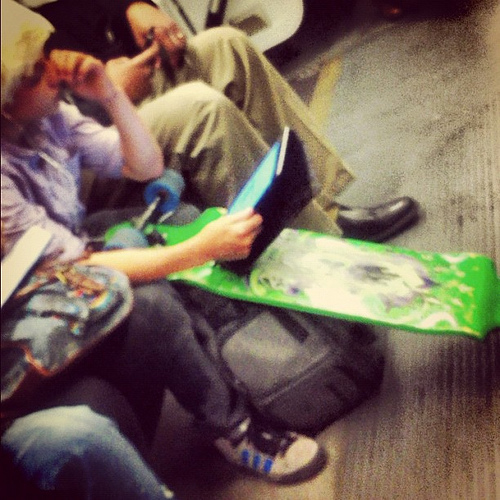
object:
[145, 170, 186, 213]
wheels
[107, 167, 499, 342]
skateboard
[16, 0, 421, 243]
man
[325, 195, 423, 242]
shoe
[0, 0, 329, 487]
boy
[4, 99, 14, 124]
earphones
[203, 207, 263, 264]
hand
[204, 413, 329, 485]
shoe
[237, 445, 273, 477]
stripes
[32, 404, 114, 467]
knee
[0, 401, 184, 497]
pants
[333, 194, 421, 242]
loafer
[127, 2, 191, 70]
hand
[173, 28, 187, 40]
ring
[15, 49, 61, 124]
face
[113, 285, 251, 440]
jeans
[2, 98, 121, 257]
shirt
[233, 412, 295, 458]
laces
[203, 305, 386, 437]
backpack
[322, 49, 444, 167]
floor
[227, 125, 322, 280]
computer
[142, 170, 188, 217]
wheel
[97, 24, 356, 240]
pants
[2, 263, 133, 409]
skateboard